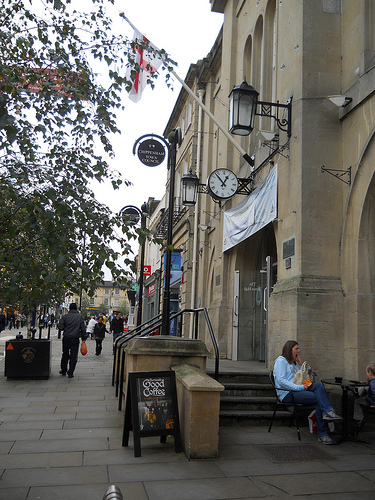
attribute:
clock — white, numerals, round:
[209, 170, 239, 201]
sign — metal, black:
[139, 139, 166, 168]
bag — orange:
[77, 336, 89, 357]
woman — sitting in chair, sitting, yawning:
[271, 339, 345, 446]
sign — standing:
[122, 372, 188, 458]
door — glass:
[242, 267, 269, 366]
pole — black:
[164, 126, 180, 336]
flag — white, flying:
[119, 33, 168, 107]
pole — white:
[116, 14, 259, 167]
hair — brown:
[282, 341, 297, 364]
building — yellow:
[123, 1, 371, 452]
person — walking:
[59, 303, 88, 379]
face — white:
[212, 172, 235, 193]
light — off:
[225, 79, 260, 137]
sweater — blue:
[273, 359, 304, 397]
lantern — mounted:
[230, 81, 292, 138]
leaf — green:
[127, 80, 134, 90]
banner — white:
[219, 164, 280, 252]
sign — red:
[141, 267, 154, 278]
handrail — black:
[197, 307, 225, 372]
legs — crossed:
[322, 375, 369, 441]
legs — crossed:
[294, 385, 338, 447]